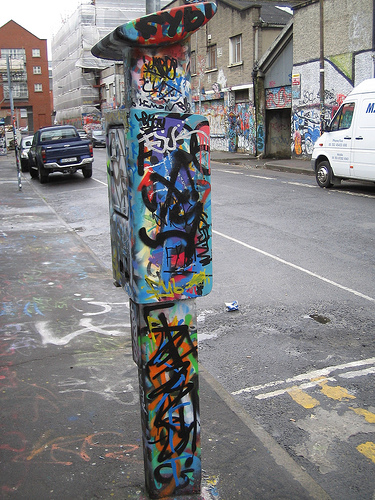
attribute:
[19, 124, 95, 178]
truck — blue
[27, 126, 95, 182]
truck — blue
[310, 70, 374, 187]
van — white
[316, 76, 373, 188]
van — one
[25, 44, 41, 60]
window — one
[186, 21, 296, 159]
building — one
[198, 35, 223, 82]
window — one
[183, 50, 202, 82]
window — one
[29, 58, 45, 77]
window — one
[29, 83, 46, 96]
window — one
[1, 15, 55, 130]
building — brick, red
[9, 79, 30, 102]
window — one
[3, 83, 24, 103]
window — one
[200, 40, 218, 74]
window — one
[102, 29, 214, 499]
post — one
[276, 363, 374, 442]
paint — yellow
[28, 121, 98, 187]
truck — blue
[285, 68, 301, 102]
sign — one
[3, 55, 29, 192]
post — metal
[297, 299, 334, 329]
spot — oil